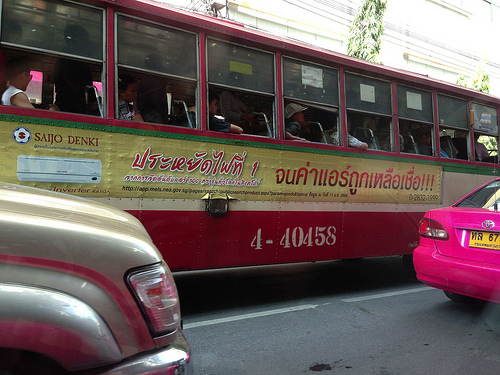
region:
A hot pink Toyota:
[392, 135, 497, 335]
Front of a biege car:
[10, 166, 185, 356]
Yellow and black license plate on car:
[451, 208, 493, 253]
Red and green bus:
[165, 71, 405, 251]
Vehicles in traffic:
[120, 125, 485, 345]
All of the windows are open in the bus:
[11, 22, 466, 172]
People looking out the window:
[5, 46, 420, 156]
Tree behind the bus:
[351, 12, 396, 63]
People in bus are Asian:
[22, 37, 487, 162]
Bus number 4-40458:
[246, 222, 351, 267]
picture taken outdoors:
[75, 78, 431, 364]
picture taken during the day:
[81, 86, 437, 339]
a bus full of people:
[101, 32, 488, 351]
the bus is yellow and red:
[127, 93, 412, 275]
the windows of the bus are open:
[178, 110, 449, 293]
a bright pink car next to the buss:
[341, 176, 467, 258]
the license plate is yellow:
[438, 185, 478, 234]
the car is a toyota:
[401, 153, 497, 268]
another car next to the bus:
[49, 194, 206, 313]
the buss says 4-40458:
[216, 196, 409, 287]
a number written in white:
[246, 221, 338, 248]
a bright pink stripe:
[9, 245, 116, 282]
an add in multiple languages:
[9, 119, 442, 213]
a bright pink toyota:
[410, 172, 499, 304]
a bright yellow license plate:
[465, 227, 499, 251]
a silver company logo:
[478, 215, 498, 234]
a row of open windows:
[33, 45, 486, 171]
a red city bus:
[14, 17, 486, 274]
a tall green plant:
[345, 0, 399, 70]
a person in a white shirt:
[1, 55, 55, 121]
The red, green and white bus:
[0, 0, 498, 280]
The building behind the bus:
[158, 0, 498, 96]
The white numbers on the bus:
[240, 221, 339, 254]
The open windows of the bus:
[0, 41, 498, 173]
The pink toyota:
[410, 176, 498, 320]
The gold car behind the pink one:
[0, 173, 204, 372]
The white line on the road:
[183, 283, 433, 333]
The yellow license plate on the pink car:
[466, 228, 498, 250]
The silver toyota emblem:
[479, 217, 498, 231]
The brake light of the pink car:
[412, 213, 452, 243]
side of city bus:
[211, 48, 439, 279]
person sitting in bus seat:
[282, 101, 317, 143]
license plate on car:
[457, 224, 495, 252]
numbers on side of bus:
[240, 220, 343, 262]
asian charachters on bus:
[112, 145, 272, 186]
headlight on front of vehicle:
[130, 254, 183, 340]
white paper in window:
[294, 64, 331, 94]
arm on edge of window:
[209, 112, 249, 144]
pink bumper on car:
[412, 256, 486, 296]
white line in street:
[237, 297, 312, 324]